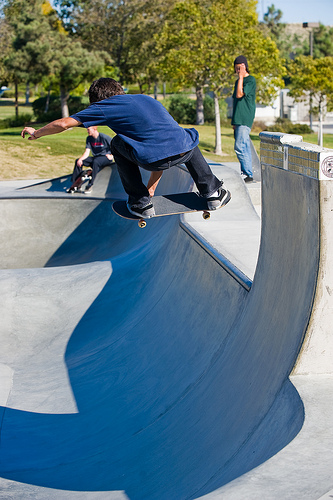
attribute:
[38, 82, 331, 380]
park — skateboard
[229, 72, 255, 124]
shirt — tee shirt, green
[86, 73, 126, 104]
hair — short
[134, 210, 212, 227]
wheels — yellow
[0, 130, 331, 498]
skate rink — curved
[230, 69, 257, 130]
shirt — green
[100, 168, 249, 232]
skateboard — black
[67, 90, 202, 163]
shirt — blue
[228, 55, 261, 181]
boy — standing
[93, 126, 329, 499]
walls — cement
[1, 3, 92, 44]
park — skateboard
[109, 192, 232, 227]
skateboard — black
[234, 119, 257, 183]
jeans — light blue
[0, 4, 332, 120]
trees — green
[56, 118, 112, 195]
person — seated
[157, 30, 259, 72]
leaves — green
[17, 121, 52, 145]
hand — extended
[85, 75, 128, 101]
hair — black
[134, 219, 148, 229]
wheel — yellow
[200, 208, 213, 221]
wheel — yellow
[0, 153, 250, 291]
rink — cement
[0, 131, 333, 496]
ramp — skateboard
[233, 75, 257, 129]
shirt — green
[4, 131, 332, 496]
skateboard ramp — pictured